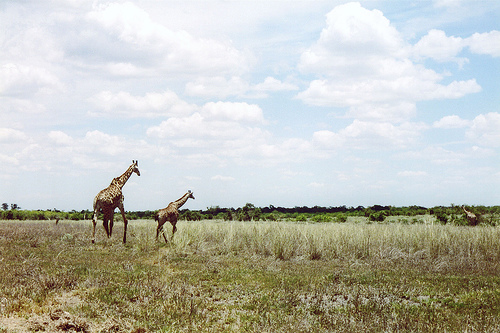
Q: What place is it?
A: It is a plain.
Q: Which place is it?
A: It is a plain.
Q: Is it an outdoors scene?
A: Yes, it is outdoors.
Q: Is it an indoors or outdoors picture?
A: It is outdoors.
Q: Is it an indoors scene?
A: No, it is outdoors.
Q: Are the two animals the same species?
A: Yes, all the animals are giraffes.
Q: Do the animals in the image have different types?
A: No, all the animals are giraffes.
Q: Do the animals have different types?
A: No, all the animals are giraffes.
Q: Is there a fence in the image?
A: No, there are no fences.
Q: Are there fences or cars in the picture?
A: No, there are no fences or cars.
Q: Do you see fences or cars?
A: No, there are no fences or cars.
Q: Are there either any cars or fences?
A: No, there are no fences or cars.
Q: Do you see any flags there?
A: No, there are no flags.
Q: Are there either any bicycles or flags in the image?
A: No, there are no flags or bicycles.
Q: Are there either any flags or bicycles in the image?
A: No, there are no flags or bicycles.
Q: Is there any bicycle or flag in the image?
A: No, there are no flags or bicycles.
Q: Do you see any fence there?
A: No, there are no fences.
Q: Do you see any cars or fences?
A: No, there are no fences or cars.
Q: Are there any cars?
A: No, there are no cars.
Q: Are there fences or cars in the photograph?
A: No, there are no cars or fences.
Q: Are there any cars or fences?
A: No, there are no cars or fences.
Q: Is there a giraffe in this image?
A: Yes, there is a giraffe.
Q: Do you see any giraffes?
A: Yes, there is a giraffe.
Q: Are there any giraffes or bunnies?
A: Yes, there is a giraffe.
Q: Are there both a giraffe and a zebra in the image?
A: No, there is a giraffe but no zebras.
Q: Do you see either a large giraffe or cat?
A: Yes, there is a large giraffe.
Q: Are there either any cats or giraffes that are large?
A: Yes, the giraffe is large.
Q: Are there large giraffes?
A: Yes, there is a large giraffe.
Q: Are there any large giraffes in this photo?
A: Yes, there is a large giraffe.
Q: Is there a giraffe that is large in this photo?
A: Yes, there is a large giraffe.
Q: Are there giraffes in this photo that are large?
A: Yes, there is a giraffe that is large.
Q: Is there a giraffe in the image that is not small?
A: Yes, there is a large giraffe.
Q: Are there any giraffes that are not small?
A: Yes, there is a large giraffe.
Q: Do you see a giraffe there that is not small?
A: Yes, there is a large giraffe.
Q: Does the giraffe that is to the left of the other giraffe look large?
A: Yes, the giraffe is large.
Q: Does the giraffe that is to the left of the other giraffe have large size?
A: Yes, the giraffe is large.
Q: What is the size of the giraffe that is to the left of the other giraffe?
A: The giraffe is large.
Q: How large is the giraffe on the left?
A: The giraffe is large.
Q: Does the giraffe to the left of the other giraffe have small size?
A: No, the giraffe is large.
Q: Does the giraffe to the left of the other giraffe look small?
A: No, the giraffe is large.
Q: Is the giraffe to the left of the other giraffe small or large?
A: The giraffe is large.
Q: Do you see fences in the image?
A: No, there are no fences.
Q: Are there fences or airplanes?
A: No, there are no fences or airplanes.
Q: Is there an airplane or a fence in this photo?
A: No, there are no fences or airplanes.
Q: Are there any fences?
A: No, there are no fences.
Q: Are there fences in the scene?
A: No, there are no fences.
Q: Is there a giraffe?
A: Yes, there is a giraffe.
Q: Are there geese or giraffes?
A: Yes, there is a giraffe.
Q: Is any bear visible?
A: No, there are no bears.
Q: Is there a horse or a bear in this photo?
A: No, there are no bears or horses.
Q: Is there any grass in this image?
A: Yes, there is grass.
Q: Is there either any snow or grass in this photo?
A: Yes, there is grass.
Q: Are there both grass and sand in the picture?
A: No, there is grass but no sand.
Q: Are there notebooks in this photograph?
A: No, there are no notebooks.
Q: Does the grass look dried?
A: Yes, the grass is dried.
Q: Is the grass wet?
A: No, the grass is dried.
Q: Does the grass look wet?
A: No, the grass is dried.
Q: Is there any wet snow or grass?
A: No, there is grass but it is dried.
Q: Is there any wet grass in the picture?
A: No, there is grass but it is dried.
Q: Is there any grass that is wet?
A: No, there is grass but it is dried.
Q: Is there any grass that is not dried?
A: No, there is grass but it is dried.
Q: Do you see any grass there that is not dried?
A: No, there is grass but it is dried.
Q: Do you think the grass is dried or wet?
A: The grass is dried.